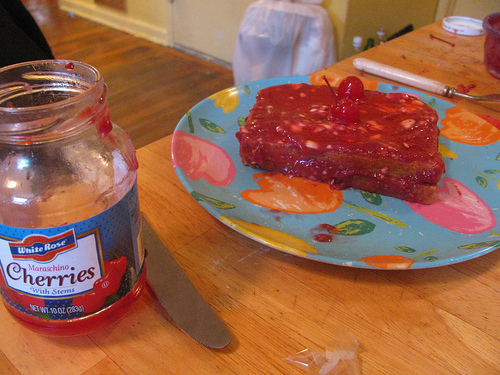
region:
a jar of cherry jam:
[7, 67, 243, 373]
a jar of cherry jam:
[5, 65, 134, 286]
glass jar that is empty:
[0, 51, 151, 356]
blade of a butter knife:
[138, 208, 233, 353]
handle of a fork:
[347, 53, 457, 97]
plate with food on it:
[164, 58, 499, 282]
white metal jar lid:
[436, 11, 489, 39]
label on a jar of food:
[0, 173, 147, 323]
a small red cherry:
[334, 73, 370, 98]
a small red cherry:
[329, 91, 362, 120]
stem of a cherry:
[427, 28, 459, 50]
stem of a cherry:
[321, 71, 340, 104]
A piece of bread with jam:
[218, 57, 468, 218]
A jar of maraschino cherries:
[1, 35, 163, 360]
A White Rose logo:
[2, 221, 87, 266]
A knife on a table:
[97, 149, 247, 369]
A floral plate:
[150, 36, 499, 293]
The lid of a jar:
[438, 7, 493, 47]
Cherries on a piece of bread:
[299, 50, 391, 152]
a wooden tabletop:
[235, 263, 362, 372]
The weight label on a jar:
[19, 294, 99, 331]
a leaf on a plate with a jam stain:
[313, 201, 375, 252]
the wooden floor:
[121, 52, 185, 105]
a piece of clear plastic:
[292, 335, 352, 374]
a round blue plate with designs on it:
[175, 70, 499, 271]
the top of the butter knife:
[141, 212, 230, 349]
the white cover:
[444, 14, 482, 36]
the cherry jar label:
[1, 221, 136, 315]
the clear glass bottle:
[2, 58, 147, 335]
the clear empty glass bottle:
[5, 60, 147, 332]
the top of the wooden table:
[369, 290, 499, 363]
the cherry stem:
[429, 32, 454, 49]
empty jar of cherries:
[0, 55, 163, 345]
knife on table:
[140, 250, 270, 365]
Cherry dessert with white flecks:
[220, 65, 460, 222]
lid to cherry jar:
[435, 5, 496, 45]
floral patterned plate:
[205, 197, 491, 278]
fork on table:
[350, 35, 490, 105]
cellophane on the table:
[272, 330, 392, 370]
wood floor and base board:
[105, 10, 181, 110]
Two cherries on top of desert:
[320, 65, 372, 127]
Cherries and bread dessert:
[227, 67, 462, 208]